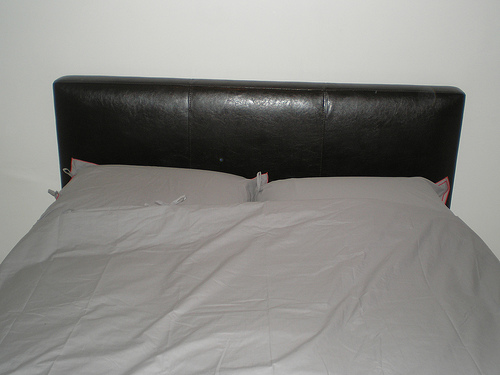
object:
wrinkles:
[136, 210, 262, 372]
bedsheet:
[2, 198, 500, 373]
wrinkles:
[269, 217, 451, 374]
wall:
[1, 0, 500, 73]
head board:
[51, 75, 465, 211]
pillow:
[48, 157, 269, 203]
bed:
[0, 74, 499, 374]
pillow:
[256, 176, 450, 205]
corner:
[71, 157, 98, 175]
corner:
[434, 176, 450, 205]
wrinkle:
[327, 101, 334, 119]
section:
[51, 75, 191, 190]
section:
[188, 79, 328, 184]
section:
[324, 82, 465, 210]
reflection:
[224, 89, 317, 114]